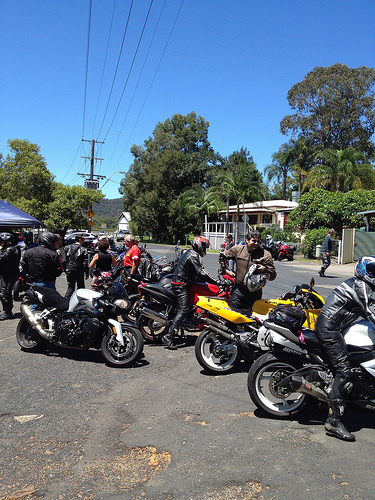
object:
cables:
[81, 0, 95, 143]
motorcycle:
[193, 275, 325, 375]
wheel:
[100, 321, 144, 366]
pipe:
[291, 374, 330, 405]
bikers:
[222, 228, 278, 312]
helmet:
[354, 254, 375, 288]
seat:
[31, 285, 70, 311]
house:
[199, 197, 305, 251]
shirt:
[121, 244, 143, 270]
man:
[318, 227, 336, 279]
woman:
[89, 238, 118, 292]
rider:
[161, 234, 221, 351]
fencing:
[340, 226, 375, 264]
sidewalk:
[283, 262, 356, 279]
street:
[0, 242, 375, 499]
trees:
[0, 136, 107, 237]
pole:
[89, 137, 95, 182]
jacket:
[224, 242, 278, 289]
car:
[115, 227, 130, 244]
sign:
[84, 205, 95, 220]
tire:
[193, 327, 241, 374]